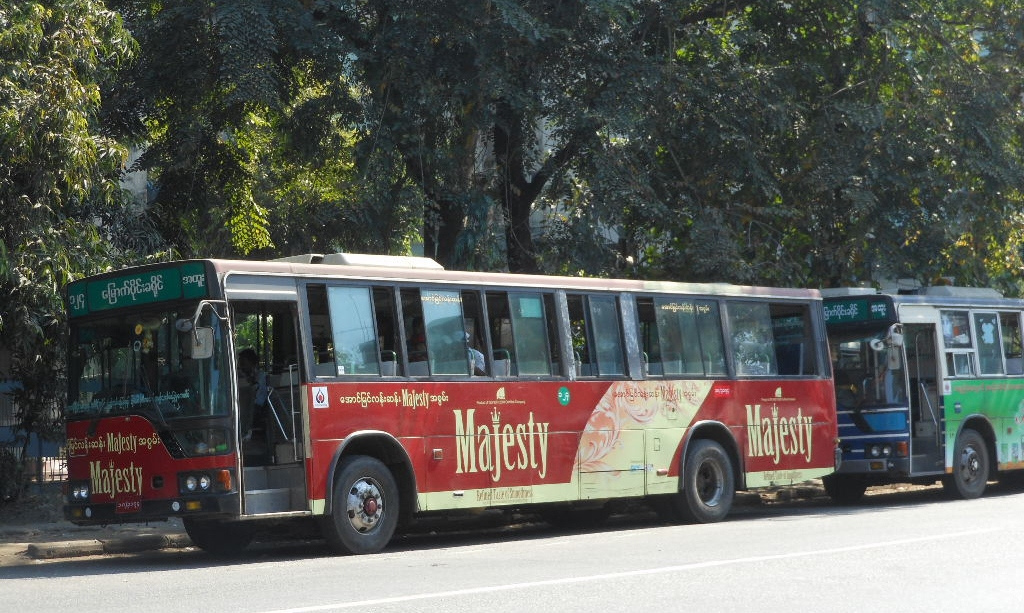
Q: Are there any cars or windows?
A: Yes, there is a window.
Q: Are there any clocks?
A: No, there are no clocks.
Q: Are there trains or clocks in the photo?
A: No, there are no clocks or trains.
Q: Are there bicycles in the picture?
A: No, there are no bicycles.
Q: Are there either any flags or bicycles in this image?
A: No, there are no bicycles or flags.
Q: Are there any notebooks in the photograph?
A: No, there are no notebooks.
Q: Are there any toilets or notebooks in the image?
A: No, there are no notebooks or toilets.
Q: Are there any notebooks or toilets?
A: No, there are no notebooks or toilets.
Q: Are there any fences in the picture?
A: No, there are no fences.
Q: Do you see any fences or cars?
A: No, there are no fences or cars.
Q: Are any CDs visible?
A: No, there are no cds.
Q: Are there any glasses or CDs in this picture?
A: No, there are no CDs or glasses.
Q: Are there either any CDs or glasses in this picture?
A: No, there are no CDs or glasses.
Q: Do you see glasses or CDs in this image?
A: No, there are no CDs or glasses.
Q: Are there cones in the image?
A: No, there are no cones.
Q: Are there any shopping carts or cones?
A: No, there are no cones or shopping carts.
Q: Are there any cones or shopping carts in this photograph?
A: No, there are no cones or shopping carts.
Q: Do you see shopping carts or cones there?
A: No, there are no cones or shopping carts.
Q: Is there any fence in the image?
A: No, there are no fences.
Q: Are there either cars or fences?
A: No, there are no fences or cars.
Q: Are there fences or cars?
A: No, there are no fences or cars.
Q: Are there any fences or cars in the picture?
A: No, there are no cars or fences.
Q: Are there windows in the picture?
A: Yes, there is a window.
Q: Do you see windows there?
A: Yes, there is a window.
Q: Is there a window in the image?
A: Yes, there is a window.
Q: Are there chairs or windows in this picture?
A: Yes, there is a window.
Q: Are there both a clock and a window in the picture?
A: No, there is a window but no clocks.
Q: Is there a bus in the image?
A: Yes, there is a bus.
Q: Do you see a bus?
A: Yes, there is a bus.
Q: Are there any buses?
A: Yes, there is a bus.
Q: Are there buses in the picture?
A: Yes, there is a bus.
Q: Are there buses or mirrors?
A: Yes, there is a bus.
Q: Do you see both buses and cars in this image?
A: No, there is a bus but no cars.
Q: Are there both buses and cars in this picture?
A: No, there is a bus but no cars.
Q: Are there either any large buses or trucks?
A: Yes, there is a large bus.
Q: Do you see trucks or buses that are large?
A: Yes, the bus is large.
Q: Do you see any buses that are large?
A: Yes, there is a large bus.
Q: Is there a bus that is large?
A: Yes, there is a bus that is large.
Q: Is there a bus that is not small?
A: Yes, there is a large bus.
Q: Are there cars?
A: No, there are no cars.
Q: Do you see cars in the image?
A: No, there are no cars.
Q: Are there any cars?
A: No, there are no cars.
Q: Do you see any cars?
A: No, there are no cars.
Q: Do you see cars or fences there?
A: No, there are no cars or fences.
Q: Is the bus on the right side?
A: Yes, the bus is on the right of the image.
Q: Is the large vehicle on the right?
A: Yes, the bus is on the right of the image.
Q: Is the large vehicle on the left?
A: No, the bus is on the right of the image.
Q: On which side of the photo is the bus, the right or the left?
A: The bus is on the right of the image.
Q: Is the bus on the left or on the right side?
A: The bus is on the right of the image.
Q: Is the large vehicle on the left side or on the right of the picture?
A: The bus is on the right of the image.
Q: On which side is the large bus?
A: The bus is on the right of the image.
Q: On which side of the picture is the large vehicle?
A: The bus is on the right of the image.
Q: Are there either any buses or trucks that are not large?
A: No, there is a bus but it is large.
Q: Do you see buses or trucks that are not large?
A: No, there is a bus but it is large.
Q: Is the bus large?
A: Yes, the bus is large.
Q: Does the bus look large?
A: Yes, the bus is large.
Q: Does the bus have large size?
A: Yes, the bus is large.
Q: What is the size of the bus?
A: The bus is large.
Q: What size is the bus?
A: The bus is large.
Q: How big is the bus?
A: The bus is large.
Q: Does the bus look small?
A: No, the bus is large.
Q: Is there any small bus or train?
A: No, there is a bus but it is large.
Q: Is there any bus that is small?
A: No, there is a bus but it is large.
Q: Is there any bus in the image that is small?
A: No, there is a bus but it is large.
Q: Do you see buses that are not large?
A: No, there is a bus but it is large.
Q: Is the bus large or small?
A: The bus is large.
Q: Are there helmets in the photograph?
A: No, there are no helmets.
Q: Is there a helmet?
A: No, there are no helmets.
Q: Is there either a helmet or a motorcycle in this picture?
A: No, there are no helmets or motorcycles.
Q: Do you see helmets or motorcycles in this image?
A: No, there are no helmets or motorcycles.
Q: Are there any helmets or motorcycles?
A: No, there are no helmets or motorcycles.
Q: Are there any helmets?
A: No, there are no helmets.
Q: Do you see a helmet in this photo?
A: No, there are no helmets.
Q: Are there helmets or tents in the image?
A: No, there are no helmets or tents.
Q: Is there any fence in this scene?
A: No, there are no fences.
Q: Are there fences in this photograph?
A: No, there are no fences.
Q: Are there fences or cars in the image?
A: No, there are no fences or cars.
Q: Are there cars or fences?
A: No, there are no fences or cars.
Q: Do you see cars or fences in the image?
A: No, there are no fences or cars.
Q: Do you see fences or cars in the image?
A: No, there are no fences or cars.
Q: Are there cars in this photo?
A: No, there are no cars.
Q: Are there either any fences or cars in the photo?
A: No, there are no cars or fences.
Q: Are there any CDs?
A: No, there are no cds.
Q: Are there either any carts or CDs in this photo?
A: No, there are no CDs or carts.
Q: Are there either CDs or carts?
A: No, there are no CDs or carts.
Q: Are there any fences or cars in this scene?
A: No, there are no fences or cars.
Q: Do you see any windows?
A: Yes, there is a window.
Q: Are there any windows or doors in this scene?
A: Yes, there is a window.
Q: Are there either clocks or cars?
A: No, there are no clocks or cars.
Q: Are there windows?
A: Yes, there is a window.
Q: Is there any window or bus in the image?
A: Yes, there is a window.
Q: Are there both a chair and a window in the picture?
A: No, there is a window but no chairs.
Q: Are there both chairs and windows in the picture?
A: No, there is a window but no chairs.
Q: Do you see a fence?
A: No, there are no fences.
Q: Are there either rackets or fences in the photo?
A: No, there are no fences or rackets.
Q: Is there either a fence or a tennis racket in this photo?
A: No, there are no fences or rackets.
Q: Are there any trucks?
A: No, there are no trucks.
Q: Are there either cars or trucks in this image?
A: No, there are no trucks or cars.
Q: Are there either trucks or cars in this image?
A: No, there are no trucks or cars.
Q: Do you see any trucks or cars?
A: No, there are no trucks or cars.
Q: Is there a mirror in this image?
A: Yes, there is a mirror.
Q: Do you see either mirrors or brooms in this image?
A: Yes, there is a mirror.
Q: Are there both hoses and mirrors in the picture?
A: No, there is a mirror but no hoses.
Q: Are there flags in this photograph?
A: No, there are no flags.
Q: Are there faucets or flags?
A: No, there are no flags or faucets.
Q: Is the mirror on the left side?
A: Yes, the mirror is on the left of the image.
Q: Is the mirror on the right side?
A: No, the mirror is on the left of the image.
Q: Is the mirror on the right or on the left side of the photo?
A: The mirror is on the left of the image.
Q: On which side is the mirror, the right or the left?
A: The mirror is on the left of the image.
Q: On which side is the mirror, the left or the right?
A: The mirror is on the left of the image.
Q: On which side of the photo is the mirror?
A: The mirror is on the left of the image.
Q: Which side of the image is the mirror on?
A: The mirror is on the left of the image.